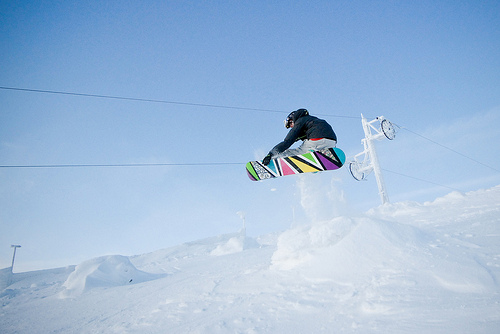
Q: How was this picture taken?
A: Camera.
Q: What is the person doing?
A: Snowboarding.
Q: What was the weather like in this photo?
A: Sunny.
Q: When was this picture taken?
A: Daylight.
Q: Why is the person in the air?
A: A snowboarder.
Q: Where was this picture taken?
A: On a ski slope.